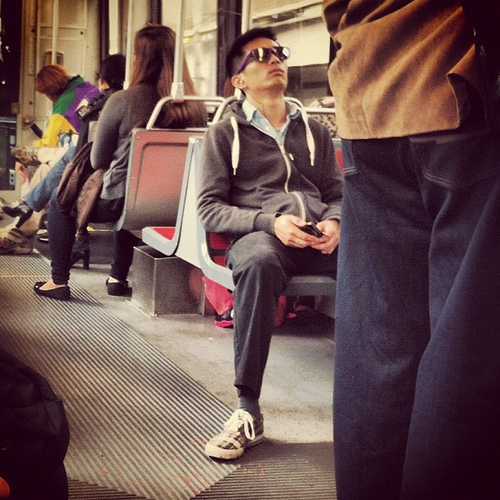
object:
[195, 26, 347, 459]
man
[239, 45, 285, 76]
sunglasses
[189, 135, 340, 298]
chair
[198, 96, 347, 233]
hoodie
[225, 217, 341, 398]
pants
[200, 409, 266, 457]
shoes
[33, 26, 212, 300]
people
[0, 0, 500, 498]
train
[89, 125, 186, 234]
seats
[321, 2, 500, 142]
jacket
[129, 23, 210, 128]
hair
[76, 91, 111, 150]
jacket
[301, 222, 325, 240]
phone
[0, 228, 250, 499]
walkway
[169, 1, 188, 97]
pole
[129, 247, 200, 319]
box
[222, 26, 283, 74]
hair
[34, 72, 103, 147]
coat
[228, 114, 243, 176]
shoestring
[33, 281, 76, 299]
slipper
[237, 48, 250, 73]
purple rim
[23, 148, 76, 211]
jeans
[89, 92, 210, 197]
shirt